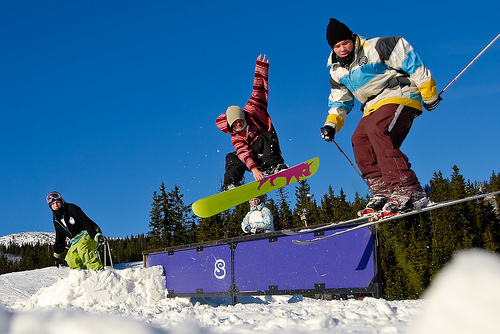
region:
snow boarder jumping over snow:
[180, 45, 323, 228]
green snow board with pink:
[187, 157, 327, 214]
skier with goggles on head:
[41, 185, 128, 297]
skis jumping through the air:
[283, 185, 493, 247]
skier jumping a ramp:
[300, 11, 464, 259]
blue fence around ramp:
[136, 245, 381, 289]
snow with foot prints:
[138, 282, 323, 325]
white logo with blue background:
[209, 250, 231, 287]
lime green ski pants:
[60, 237, 109, 272]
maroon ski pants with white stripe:
[346, 112, 426, 193]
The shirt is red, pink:
[183, 30, 294, 180]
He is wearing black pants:
[187, 122, 291, 192]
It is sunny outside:
[11, 8, 476, 246]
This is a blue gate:
[70, 205, 462, 303]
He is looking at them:
[27, 166, 118, 276]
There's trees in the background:
[28, 168, 443, 302]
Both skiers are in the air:
[181, 18, 476, 245]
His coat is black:
[24, 162, 111, 259]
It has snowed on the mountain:
[4, 227, 466, 331]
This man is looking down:
[313, 12, 431, 206]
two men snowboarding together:
[170, 27, 417, 214]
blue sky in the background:
[60, 42, 190, 119]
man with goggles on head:
[33, 164, 103, 246]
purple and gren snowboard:
[194, 153, 324, 235]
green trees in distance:
[428, 165, 485, 238]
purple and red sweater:
[246, 96, 272, 132]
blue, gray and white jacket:
[356, 26, 416, 109]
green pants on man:
[56, 235, 104, 266]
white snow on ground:
[71, 284, 153, 331]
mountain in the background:
[17, 225, 37, 252]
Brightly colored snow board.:
[176, 155, 337, 221]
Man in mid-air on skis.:
[285, 14, 475, 275]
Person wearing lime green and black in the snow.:
[37, 172, 119, 294]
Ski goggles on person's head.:
[41, 186, 71, 216]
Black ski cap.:
[320, 15, 357, 51]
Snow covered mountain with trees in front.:
[0, 229, 57, 259]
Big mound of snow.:
[34, 272, 164, 311]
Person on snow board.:
[182, 48, 327, 236]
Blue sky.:
[0, 0, 497, 157]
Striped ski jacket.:
[305, 35, 455, 138]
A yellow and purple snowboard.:
[191, 154, 321, 217]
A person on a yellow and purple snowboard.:
[214, 52, 289, 192]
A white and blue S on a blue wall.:
[210, 257, 228, 279]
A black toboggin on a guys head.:
[325, 14, 354, 49]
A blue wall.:
[140, 215, 386, 299]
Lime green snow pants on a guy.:
[63, 234, 107, 271]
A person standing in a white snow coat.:
[239, 194, 275, 235]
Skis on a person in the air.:
[280, 189, 499, 248]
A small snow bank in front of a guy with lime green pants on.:
[15, 264, 169, 319]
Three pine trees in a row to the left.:
[147, 180, 193, 255]